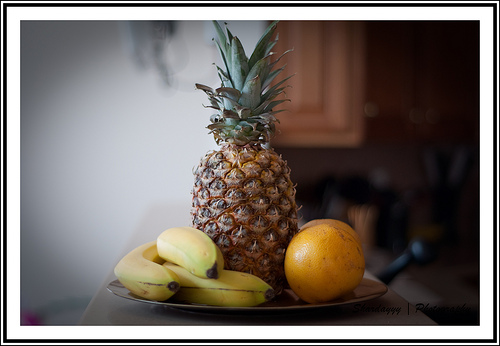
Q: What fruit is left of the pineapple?
A: Bananas.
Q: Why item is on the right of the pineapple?
A: An orange.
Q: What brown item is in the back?
A: A cabinet.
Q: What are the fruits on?
A: A plate.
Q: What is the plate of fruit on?
A: The counter.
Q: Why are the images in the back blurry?
A: The plate of fruit is in the focus.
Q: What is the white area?
A: The wall.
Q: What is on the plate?
A: Pineapple.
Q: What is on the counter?
A: Fruit.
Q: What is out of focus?
A: Cabinet.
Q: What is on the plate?
A: Bananas.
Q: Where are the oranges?
A: Plate.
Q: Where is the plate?
A: Coutner.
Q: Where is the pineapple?
A: Plate.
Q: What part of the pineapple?
A: Top.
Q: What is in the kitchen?
A: Cabinet.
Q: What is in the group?
A: Fruits.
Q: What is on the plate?
A: Fruit.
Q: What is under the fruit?
A: The plate.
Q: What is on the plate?
A: Pineapple.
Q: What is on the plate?
A: Banana.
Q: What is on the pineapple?
A: A stem.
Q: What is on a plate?
A: Bananas.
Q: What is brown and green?
A: A pineapple.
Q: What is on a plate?
A: Fruit.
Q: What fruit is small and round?
A: An orange.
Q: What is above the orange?
A: A cupboard.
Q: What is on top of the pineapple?
A: Leaves.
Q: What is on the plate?
A: Assorted fruit.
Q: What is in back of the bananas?
A: A wall.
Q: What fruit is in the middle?
A: An pineapple.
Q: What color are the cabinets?
A: Brown.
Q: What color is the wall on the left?
A: White.